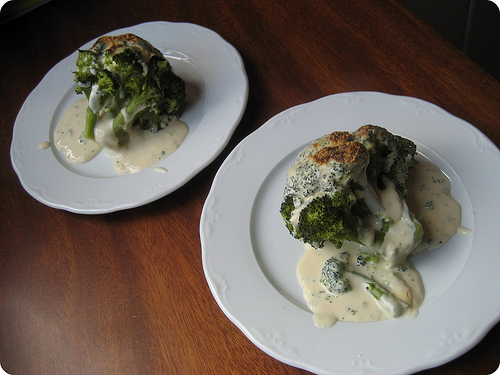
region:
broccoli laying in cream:
[52, 30, 202, 182]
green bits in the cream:
[343, 305, 356, 315]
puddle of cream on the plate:
[42, 100, 192, 175]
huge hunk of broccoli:
[261, 118, 446, 255]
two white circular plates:
[8, 19, 498, 373]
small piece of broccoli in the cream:
[319, 255, 408, 316]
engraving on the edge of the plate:
[337, 348, 389, 373]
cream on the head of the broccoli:
[276, 159, 347, 229]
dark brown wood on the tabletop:
[3, 4, 498, 373]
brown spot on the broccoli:
[313, 140, 363, 165]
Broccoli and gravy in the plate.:
[306, 153, 421, 338]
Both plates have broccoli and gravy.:
[91, 35, 382, 292]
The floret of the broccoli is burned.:
[313, 133, 368, 164]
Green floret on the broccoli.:
[116, 77, 171, 107]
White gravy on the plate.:
[302, 258, 419, 313]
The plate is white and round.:
[244, 105, 477, 316]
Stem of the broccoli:
[81, 95, 130, 130]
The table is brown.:
[25, 234, 200, 361]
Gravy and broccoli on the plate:
[65, 57, 171, 146]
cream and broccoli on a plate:
[271, 104, 430, 294]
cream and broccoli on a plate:
[86, 67, 150, 122]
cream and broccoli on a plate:
[295, 144, 416, 240]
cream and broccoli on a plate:
[81, 48, 178, 132]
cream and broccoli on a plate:
[271, 128, 392, 238]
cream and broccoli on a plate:
[57, 29, 184, 124]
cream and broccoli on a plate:
[273, 125, 388, 249]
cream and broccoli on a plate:
[70, 83, 178, 176]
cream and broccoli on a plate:
[349, 113, 439, 228]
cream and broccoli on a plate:
[112, 57, 172, 132]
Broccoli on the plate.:
[280, 128, 449, 315]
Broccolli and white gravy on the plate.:
[301, 139, 456, 322]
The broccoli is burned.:
[301, 123, 385, 173]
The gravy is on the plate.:
[296, 265, 439, 338]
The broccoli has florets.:
[70, 48, 173, 130]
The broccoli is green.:
[63, 41, 153, 143]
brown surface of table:
[5, 7, 495, 367]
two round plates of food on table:
[5, 15, 495, 367]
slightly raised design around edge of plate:
[197, 90, 492, 370]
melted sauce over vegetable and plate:
[280, 125, 470, 327]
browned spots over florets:
[310, 120, 415, 175]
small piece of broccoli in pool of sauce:
[296, 252, 416, 317]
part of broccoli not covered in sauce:
[310, 196, 350, 237]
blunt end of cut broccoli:
[380, 210, 425, 266]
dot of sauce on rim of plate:
[31, 136, 51, 151]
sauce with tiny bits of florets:
[421, 170, 457, 241]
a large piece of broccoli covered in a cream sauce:
[271, 115, 439, 270]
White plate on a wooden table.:
[203, 90, 499, 372]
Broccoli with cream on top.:
[278, 124, 423, 262]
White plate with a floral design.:
[9, 20, 249, 215]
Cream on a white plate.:
[297, 160, 472, 327]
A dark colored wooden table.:
[0, 3, 499, 373]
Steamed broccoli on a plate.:
[71, 34, 191, 145]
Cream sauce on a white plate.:
[39, 94, 188, 186]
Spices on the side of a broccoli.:
[309, 124, 399, 171]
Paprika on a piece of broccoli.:
[94, 33, 161, 69]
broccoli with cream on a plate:
[97, 50, 134, 108]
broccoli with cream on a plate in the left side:
[92, 61, 137, 116]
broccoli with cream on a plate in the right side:
[312, 161, 377, 236]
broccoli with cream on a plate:
[295, 162, 395, 240]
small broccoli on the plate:
[323, 262, 377, 297]